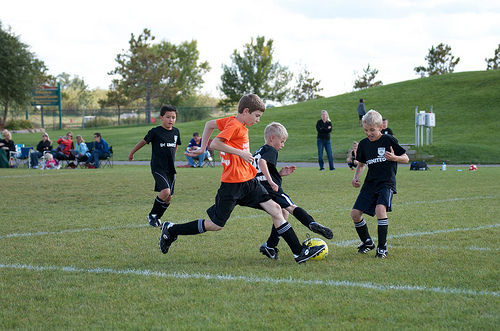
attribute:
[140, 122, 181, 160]
shirt — black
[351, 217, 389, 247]
socks — black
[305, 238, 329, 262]
soccer ball — yellow 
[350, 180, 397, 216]
shorts — black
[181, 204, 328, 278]
shoes — black, white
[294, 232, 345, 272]
ball — yellow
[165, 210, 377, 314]
shoes — white, black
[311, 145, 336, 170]
jeans — blue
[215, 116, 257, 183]
shirt — orange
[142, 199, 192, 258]
shoes — black 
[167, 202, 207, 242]
sock — black 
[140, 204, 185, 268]
shoe — black 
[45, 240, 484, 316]
line — white 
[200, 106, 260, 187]
shirt — orange 